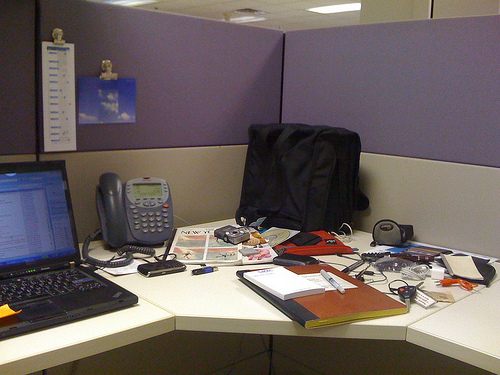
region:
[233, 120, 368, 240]
black bag on the desk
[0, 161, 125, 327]
black laptop open on the desk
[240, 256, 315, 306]
white notepad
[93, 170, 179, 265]
gray telephone on the desk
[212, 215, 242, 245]
silver camera on the desk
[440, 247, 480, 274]
white spiral notepad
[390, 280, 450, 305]
car key and key chains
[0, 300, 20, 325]
yellow sticky note on laptop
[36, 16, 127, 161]
two clipboards on cubicle wall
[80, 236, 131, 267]
gray cord of the telephone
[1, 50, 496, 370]
computer and items on desk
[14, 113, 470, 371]
desk is white with 3 sides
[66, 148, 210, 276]
grey phone on desk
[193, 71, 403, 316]
black bag on desk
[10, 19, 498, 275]
two toned desk wall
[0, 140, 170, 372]
open laptop on desk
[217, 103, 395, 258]
open laptop is black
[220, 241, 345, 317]
white notepad on desk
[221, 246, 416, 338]
brown book on desk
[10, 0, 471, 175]
light purple desk wall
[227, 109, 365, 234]
Black bag on the desk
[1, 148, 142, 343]
Laptop on the desk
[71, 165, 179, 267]
Phone on the desk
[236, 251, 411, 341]
Notebook on top of desk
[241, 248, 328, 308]
Notepad on top of the notebook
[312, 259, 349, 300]
Pen on top of the notebook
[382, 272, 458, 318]
Keys on the desk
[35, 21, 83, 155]
Paper hanging on the wall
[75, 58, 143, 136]
Paper hanging on the wall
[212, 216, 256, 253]
Camera on top of desk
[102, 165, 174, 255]
phone on the table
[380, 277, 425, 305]
keys on the table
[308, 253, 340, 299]
pen on the notebook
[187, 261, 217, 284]
battery on the table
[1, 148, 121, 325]
laptop on the table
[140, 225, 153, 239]
key on the phone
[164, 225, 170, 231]
key on the phone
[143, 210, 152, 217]
key on the phone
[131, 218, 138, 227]
key on the phone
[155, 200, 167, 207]
key on the phone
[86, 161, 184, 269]
the phone on the desk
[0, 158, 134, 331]
the laptop on the desk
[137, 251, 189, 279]
the balck cellphone on the white table top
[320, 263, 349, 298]
the white pen on the notebook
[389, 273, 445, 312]
the keys on the top of the desk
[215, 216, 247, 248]
the small silver camera on the magazine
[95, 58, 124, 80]
the clip on the wall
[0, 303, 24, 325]
an orange sticker on the laptop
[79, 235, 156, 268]
the chord of the phone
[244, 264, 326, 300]
the white notepad on the desk